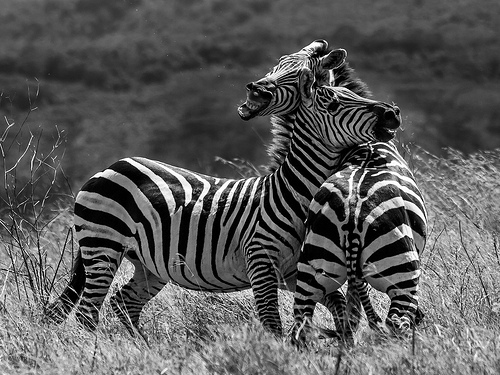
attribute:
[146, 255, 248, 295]
stomach — round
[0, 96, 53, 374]
grass — white, tall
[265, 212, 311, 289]
chest — white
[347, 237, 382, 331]
tail — long, black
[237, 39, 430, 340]
zebra — striped